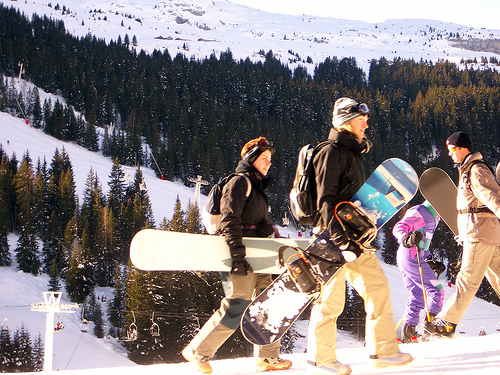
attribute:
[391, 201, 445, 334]
snowsuit — purple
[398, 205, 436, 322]
suit — purple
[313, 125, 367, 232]
jacket — black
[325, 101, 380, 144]
hat — man's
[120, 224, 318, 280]
snowboard — white and gray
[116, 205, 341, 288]
snowboard — white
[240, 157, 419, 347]
snowboard — blue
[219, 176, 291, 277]
ski jacket — dark colored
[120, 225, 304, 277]
snowboard — white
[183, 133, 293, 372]
person — one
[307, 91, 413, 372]
person — one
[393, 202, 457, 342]
person — one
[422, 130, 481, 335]
person — one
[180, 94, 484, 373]
group — people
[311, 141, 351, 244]
arm — man's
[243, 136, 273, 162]
ski googles — red, pair